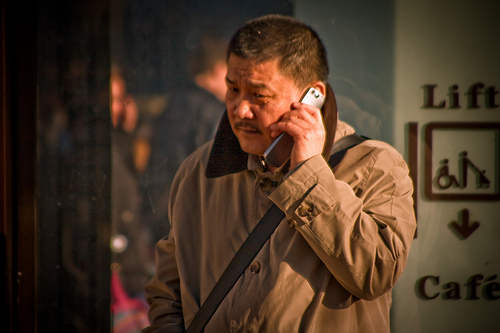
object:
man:
[146, 15, 420, 331]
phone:
[263, 86, 325, 168]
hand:
[270, 102, 327, 169]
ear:
[312, 80, 326, 97]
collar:
[203, 110, 247, 180]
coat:
[144, 84, 417, 332]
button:
[249, 261, 261, 275]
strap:
[189, 132, 363, 330]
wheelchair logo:
[436, 157, 461, 189]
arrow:
[449, 208, 482, 239]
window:
[37, 2, 393, 332]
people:
[36, 48, 140, 296]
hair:
[224, 13, 328, 89]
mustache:
[233, 120, 263, 135]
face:
[224, 56, 301, 157]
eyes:
[252, 91, 272, 99]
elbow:
[341, 225, 413, 302]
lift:
[420, 80, 498, 110]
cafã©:
[417, 274, 499, 301]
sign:
[390, 1, 499, 332]